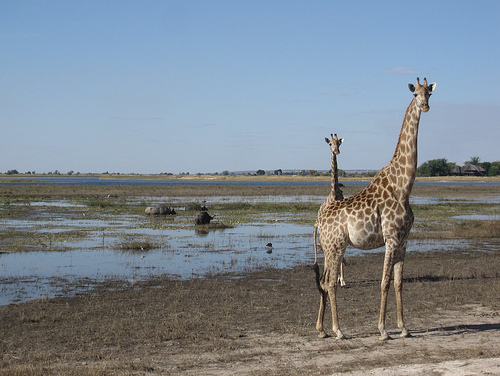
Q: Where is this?
A: This is at the swamp.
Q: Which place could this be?
A: It is a swamp.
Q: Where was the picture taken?
A: It was taken at the swamp.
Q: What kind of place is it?
A: It is a swamp.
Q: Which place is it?
A: It is a swamp.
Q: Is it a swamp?
A: Yes, it is a swamp.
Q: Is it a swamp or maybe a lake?
A: It is a swamp.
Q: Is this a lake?
A: No, it is a swamp.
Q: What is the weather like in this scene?
A: It is clear.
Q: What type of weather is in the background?
A: It is clear.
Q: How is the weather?
A: It is clear.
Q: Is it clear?
A: Yes, it is clear.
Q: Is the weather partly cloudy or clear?
A: It is clear.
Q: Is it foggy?
A: No, it is clear.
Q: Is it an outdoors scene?
A: Yes, it is outdoors.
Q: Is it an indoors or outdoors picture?
A: It is outdoors.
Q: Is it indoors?
A: No, it is outdoors.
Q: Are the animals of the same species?
A: Yes, all the animals are giraffes.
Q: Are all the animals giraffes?
A: Yes, all the animals are giraffes.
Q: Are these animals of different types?
A: No, all the animals are giraffes.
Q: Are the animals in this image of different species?
A: No, all the animals are giraffes.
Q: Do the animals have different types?
A: No, all the animals are giraffes.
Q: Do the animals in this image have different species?
A: No, all the animals are giraffes.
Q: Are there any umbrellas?
A: No, there are no umbrellas.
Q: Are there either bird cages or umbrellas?
A: No, there are no umbrellas or bird cages.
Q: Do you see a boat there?
A: No, there are no boats.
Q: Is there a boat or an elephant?
A: No, there are no boats or elephants.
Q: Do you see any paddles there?
A: No, there are no paddles.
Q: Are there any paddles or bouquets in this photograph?
A: No, there are no paddles or bouquets.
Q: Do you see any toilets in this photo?
A: No, there are no toilets.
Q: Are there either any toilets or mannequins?
A: No, there are no toilets or mannequins.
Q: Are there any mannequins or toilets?
A: No, there are no toilets or mannequins.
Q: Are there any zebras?
A: No, there are no zebras.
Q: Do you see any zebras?
A: No, there are no zebras.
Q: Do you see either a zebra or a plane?
A: No, there are no zebras or airplanes.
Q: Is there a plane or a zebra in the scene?
A: No, there are no zebras or airplanes.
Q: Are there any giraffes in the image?
A: Yes, there is a giraffe.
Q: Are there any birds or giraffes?
A: Yes, there is a giraffe.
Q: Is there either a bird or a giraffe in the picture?
A: Yes, there is a giraffe.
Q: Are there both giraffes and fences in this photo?
A: No, there is a giraffe but no fences.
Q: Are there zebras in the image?
A: No, there are no zebras.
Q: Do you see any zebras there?
A: No, there are no zebras.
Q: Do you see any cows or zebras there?
A: No, there are no zebras or cows.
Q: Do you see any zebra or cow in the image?
A: No, there are no zebras or cows.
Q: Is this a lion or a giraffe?
A: This is a giraffe.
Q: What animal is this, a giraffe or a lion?
A: This is a giraffe.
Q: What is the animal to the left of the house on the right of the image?
A: The animal is a giraffe.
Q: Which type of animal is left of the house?
A: The animal is a giraffe.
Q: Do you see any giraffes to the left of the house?
A: Yes, there is a giraffe to the left of the house.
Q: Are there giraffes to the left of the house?
A: Yes, there is a giraffe to the left of the house.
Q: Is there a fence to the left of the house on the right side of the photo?
A: No, there is a giraffe to the left of the house.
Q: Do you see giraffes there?
A: Yes, there is a giraffe.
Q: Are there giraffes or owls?
A: Yes, there is a giraffe.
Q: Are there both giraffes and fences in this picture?
A: No, there is a giraffe but no fences.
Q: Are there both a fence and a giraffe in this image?
A: No, there is a giraffe but no fences.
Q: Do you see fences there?
A: No, there are no fences.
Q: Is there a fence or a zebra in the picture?
A: No, there are no fences or zebras.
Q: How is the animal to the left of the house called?
A: The animal is a giraffe.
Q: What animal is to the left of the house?
A: The animal is a giraffe.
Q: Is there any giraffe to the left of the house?
A: Yes, there is a giraffe to the left of the house.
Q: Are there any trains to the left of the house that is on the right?
A: No, there is a giraffe to the left of the house.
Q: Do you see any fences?
A: No, there are no fences.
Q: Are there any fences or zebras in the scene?
A: No, there are no fences or zebras.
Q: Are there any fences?
A: No, there are no fences.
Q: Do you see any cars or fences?
A: No, there are no fences or cars.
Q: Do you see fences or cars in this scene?
A: No, there are no fences or cars.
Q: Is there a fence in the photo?
A: No, there are no fences.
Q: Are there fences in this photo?
A: No, there are no fences.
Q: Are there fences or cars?
A: No, there are no fences or cars.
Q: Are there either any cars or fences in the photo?
A: No, there are no fences or cars.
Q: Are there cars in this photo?
A: No, there are no cars.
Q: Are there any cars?
A: No, there are no cars.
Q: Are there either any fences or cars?
A: No, there are no cars or fences.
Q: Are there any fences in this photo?
A: No, there are no fences.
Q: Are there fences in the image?
A: No, there are no fences.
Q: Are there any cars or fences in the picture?
A: No, there are no fences or cars.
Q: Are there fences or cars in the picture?
A: No, there are no fences or cars.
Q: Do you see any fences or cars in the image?
A: No, there are no fences or cars.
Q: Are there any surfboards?
A: No, there are no surfboards.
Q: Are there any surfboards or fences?
A: No, there are no surfboards or fences.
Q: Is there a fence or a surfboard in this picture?
A: No, there are no surfboards or fences.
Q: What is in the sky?
A: The clouds are in the sky.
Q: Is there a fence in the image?
A: No, there are no fences.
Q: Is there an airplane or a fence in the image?
A: No, there are no fences or airplanes.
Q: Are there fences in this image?
A: No, there are no fences.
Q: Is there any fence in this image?
A: No, there are no fences.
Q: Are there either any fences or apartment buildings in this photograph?
A: No, there are no fences or apartment buildings.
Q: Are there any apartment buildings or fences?
A: No, there are no fences or apartment buildings.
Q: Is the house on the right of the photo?
A: Yes, the house is on the right of the image.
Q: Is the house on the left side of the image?
A: No, the house is on the right of the image.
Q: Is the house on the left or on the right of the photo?
A: The house is on the right of the image.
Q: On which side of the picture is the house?
A: The house is on the right of the image.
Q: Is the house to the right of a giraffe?
A: Yes, the house is to the right of a giraffe.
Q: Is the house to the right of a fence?
A: No, the house is to the right of a giraffe.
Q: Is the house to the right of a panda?
A: No, the house is to the right of a giraffe.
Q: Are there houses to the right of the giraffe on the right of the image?
A: Yes, there is a house to the right of the giraffe.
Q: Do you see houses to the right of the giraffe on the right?
A: Yes, there is a house to the right of the giraffe.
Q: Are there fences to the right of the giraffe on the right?
A: No, there is a house to the right of the giraffe.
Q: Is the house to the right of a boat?
A: No, the house is to the right of a giraffe.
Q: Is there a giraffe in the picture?
A: Yes, there is a giraffe.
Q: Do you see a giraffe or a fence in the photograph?
A: Yes, there is a giraffe.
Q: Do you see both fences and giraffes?
A: No, there is a giraffe but no fences.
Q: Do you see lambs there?
A: No, there are no lambs.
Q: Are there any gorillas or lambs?
A: No, there are no lambs or gorillas.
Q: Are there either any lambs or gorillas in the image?
A: No, there are no lambs or gorillas.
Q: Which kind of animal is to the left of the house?
A: The animal is a giraffe.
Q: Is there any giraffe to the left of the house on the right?
A: Yes, there is a giraffe to the left of the house.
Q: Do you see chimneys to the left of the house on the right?
A: No, there is a giraffe to the left of the house.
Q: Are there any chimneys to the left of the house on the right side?
A: No, there is a giraffe to the left of the house.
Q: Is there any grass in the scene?
A: Yes, there is grass.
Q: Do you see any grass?
A: Yes, there is grass.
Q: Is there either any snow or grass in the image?
A: Yes, there is grass.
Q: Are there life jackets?
A: No, there are no life jackets.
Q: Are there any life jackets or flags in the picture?
A: No, there are no life jackets or flags.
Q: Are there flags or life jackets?
A: No, there are no life jackets or flags.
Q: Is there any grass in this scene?
A: Yes, there is grass.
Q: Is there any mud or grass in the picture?
A: Yes, there is grass.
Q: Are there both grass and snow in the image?
A: No, there is grass but no snow.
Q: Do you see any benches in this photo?
A: No, there are no benches.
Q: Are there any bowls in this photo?
A: No, there are no bowls.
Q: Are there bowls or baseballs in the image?
A: No, there are no bowls or baseballs.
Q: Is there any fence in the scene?
A: No, there are no fences.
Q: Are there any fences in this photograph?
A: No, there are no fences.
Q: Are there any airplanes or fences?
A: No, there are no fences or airplanes.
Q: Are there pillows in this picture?
A: No, there are no pillows.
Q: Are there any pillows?
A: No, there are no pillows.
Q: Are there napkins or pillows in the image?
A: No, there are no pillows or napkins.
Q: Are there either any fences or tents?
A: No, there are no fences or tents.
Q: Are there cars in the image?
A: No, there are no cars.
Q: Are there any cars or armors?
A: No, there are no cars or armors.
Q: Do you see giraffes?
A: Yes, there is a giraffe.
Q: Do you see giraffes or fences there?
A: Yes, there is a giraffe.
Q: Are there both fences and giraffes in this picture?
A: No, there is a giraffe but no fences.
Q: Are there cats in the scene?
A: No, there are no cats.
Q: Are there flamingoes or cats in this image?
A: No, there are no cats or flamingoes.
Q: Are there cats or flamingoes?
A: No, there are no cats or flamingoes.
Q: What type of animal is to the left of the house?
A: The animal is a giraffe.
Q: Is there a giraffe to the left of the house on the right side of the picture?
A: Yes, there is a giraffe to the left of the house.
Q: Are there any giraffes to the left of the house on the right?
A: Yes, there is a giraffe to the left of the house.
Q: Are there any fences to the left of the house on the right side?
A: No, there is a giraffe to the left of the house.